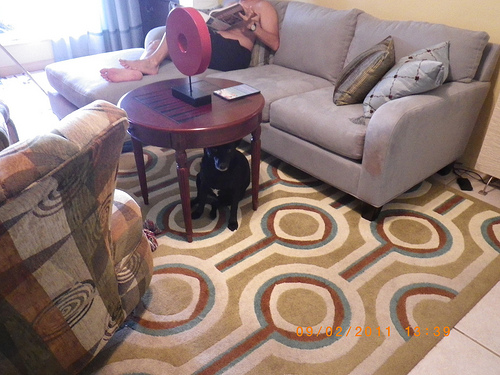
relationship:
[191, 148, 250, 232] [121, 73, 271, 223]
dog under table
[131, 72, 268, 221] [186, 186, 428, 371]
table on rug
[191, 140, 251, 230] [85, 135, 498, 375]
dog on rug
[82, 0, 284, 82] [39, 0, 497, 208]
person on couch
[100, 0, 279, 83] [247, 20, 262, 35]
person wearing a watch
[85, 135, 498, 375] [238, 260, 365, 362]
rug has a pattern